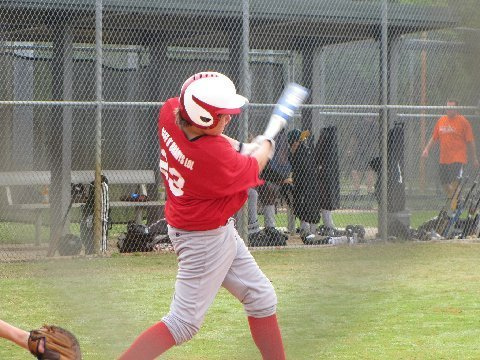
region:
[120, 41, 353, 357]
Young man playing baseball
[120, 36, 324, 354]
baseball player hitting ball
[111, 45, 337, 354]
baseball player in red and grey uniform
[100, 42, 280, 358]
baseball player in white and red helmet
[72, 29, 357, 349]
Male baseball player mid-swing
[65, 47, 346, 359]
baseball player in high red sock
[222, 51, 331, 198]
metal baseball bat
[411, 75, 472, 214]
man in orange and white shirt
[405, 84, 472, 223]
man in orange shirt and black shorts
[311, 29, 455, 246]
gray metal fence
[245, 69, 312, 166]
Player is swinging a bat.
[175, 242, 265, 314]
The pants are white.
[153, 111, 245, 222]
The jersey is red.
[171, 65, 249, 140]
Batter is wearing a helmet.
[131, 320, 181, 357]
The socks are red.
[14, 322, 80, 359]
Person is wearing a mitt.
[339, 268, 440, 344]
The grass is green.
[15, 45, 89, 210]
The fence is grey.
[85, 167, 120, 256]
Rust on the pole.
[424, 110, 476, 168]
Guy is wearing an orange shirt.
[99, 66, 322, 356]
a baseball player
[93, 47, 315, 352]
a baseball player swinging his bat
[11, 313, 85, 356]
a catcher's mitt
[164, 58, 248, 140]
man wearing a white and red helmet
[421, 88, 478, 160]
man wearing an orange shirt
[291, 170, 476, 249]
baseball equipement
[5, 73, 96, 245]
a gray metal fence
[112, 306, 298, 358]
baseball player wearing red long socks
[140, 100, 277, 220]
baseball player wearing a red uniform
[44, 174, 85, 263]
a baseball bat propped on a fence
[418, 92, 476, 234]
A man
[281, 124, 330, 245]
A man in a black jacket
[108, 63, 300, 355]
A man in a red tshirt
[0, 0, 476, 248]
A wiremesh fence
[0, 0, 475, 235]
A wire mesh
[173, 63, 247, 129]
A protective helmet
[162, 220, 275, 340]
White pants in the picture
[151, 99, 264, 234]
Red Tshirt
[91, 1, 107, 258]
A tall post on the fence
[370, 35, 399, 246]
A tall post on the fence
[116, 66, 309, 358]
basball player swinging the bat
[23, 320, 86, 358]
catcher's hand with basball glove on it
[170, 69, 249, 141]
batter wearing a helmet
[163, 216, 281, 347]
white baseball pants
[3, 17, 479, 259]
fence in front of dugout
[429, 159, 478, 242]
bats in the dugout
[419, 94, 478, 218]
man in orange shirt walking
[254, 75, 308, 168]
blurry bat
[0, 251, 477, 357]
field of green grass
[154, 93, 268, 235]
red basball jersey